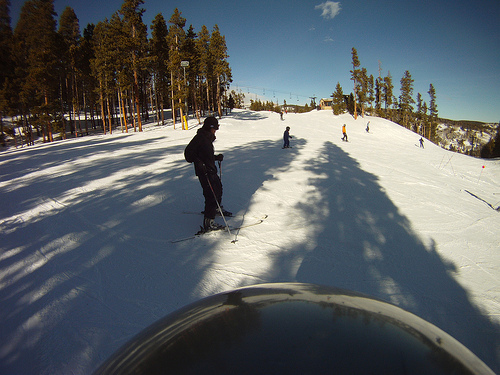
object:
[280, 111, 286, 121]
person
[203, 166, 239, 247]
ski pole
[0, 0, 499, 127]
sky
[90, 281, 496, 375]
snowmobile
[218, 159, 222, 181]
ski poles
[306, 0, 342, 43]
clouds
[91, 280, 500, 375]
helmet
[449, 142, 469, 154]
people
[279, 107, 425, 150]
skiers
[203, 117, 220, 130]
hat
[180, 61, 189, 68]
light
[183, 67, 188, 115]
pole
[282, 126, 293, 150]
kid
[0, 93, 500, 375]
snow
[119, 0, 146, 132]
tree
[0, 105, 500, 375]
hillside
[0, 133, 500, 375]
shadow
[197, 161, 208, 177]
hands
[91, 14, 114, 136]
tree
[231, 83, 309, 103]
ski lift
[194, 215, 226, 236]
ski boot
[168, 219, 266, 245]
skis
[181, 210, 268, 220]
skis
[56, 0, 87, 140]
tree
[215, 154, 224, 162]
glove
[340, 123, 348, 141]
person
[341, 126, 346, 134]
orange coat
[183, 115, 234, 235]
person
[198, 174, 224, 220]
pants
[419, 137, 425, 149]
person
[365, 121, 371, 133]
person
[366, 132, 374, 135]
skis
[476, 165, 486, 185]
red flag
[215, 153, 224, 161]
hand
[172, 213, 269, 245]
ski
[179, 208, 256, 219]
ski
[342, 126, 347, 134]
sweater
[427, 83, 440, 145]
tree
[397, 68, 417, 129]
tree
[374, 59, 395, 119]
tree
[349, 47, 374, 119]
tree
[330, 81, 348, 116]
tree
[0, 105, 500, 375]
slope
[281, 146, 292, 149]
skis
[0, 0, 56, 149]
tree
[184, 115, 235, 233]
clothing